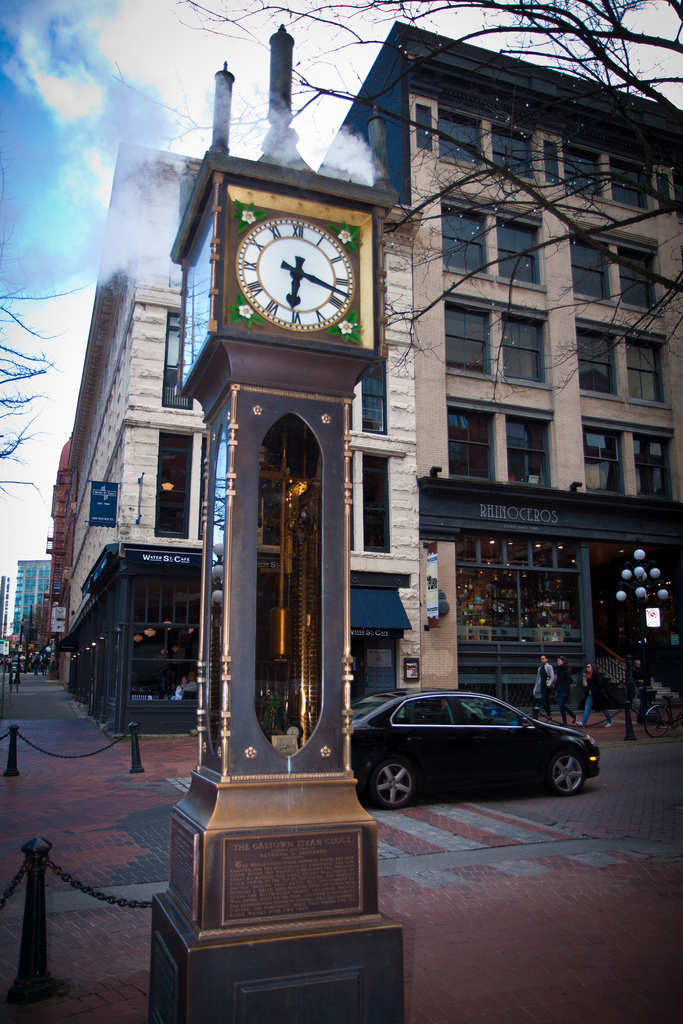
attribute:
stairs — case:
[596, 652, 681, 704]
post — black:
[8, 830, 59, 993]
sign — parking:
[644, 606, 661, 628]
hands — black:
[274, 253, 334, 312]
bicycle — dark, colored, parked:
[624, 689, 680, 740]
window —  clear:
[462, 690, 506, 724]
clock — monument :
[219, 199, 359, 360]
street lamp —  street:
[613, 547, 669, 740]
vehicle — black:
[349, 678, 606, 812]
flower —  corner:
[241, 205, 250, 223]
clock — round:
[231, 208, 354, 332]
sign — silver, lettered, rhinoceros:
[217, 167, 370, 328]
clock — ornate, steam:
[223, 211, 351, 331]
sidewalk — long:
[10, 661, 680, 761]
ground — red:
[409, 876, 661, 1018]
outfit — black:
[526, 663, 558, 724]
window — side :
[388, 693, 460, 728]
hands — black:
[284, 254, 311, 316]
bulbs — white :
[609, 532, 673, 601]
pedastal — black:
[203, 378, 409, 1021]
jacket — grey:
[528, 658, 564, 687]